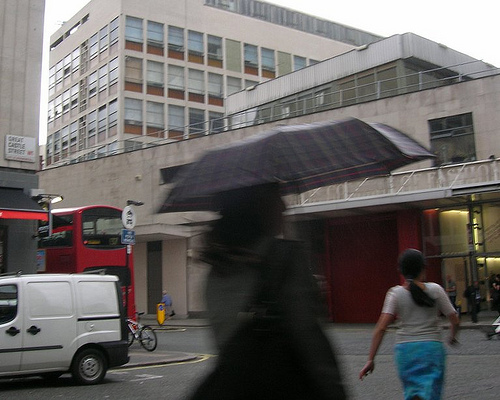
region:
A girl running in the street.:
[356, 246, 461, 398]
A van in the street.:
[0, 270, 132, 385]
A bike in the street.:
[124, 308, 158, 351]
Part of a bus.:
[35, 203, 137, 332]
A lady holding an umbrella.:
[152, 114, 438, 399]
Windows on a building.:
[44, 0, 325, 168]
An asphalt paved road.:
[0, 323, 499, 398]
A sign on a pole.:
[118, 205, 138, 320]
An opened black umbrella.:
[153, 114, 436, 216]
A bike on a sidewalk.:
[121, 309, 158, 351]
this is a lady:
[369, 242, 464, 391]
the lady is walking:
[367, 238, 466, 394]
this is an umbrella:
[296, 115, 387, 172]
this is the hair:
[405, 281, 433, 302]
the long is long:
[406, 279, 436, 312]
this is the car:
[34, 283, 106, 359]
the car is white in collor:
[39, 280, 103, 334]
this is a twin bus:
[67, 203, 118, 263]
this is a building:
[85, 23, 188, 114]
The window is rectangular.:
[121, 13, 146, 57]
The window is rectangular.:
[141, 15, 168, 57]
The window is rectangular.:
[163, 18, 187, 67]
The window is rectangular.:
[184, 22, 208, 69]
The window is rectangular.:
[206, 26, 226, 72]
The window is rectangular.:
[206, 66, 228, 113]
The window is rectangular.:
[186, 63, 206, 107]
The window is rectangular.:
[166, 59, 187, 104]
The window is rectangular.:
[145, 52, 166, 102]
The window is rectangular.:
[122, 48, 147, 97]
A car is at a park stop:
[15, 249, 113, 353]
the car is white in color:
[6, 255, 147, 397]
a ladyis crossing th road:
[393, 241, 458, 398]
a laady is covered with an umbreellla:
[201, 117, 311, 399]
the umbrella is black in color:
[257, 99, 417, 184]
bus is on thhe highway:
[68, 186, 178, 279]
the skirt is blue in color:
[383, 344, 454, 399]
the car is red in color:
[71, 187, 160, 277]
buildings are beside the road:
[133, 52, 492, 194]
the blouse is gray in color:
[381, 278, 450, 355]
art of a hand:
[283, 336, 315, 391]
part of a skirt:
[395, 351, 402, 363]